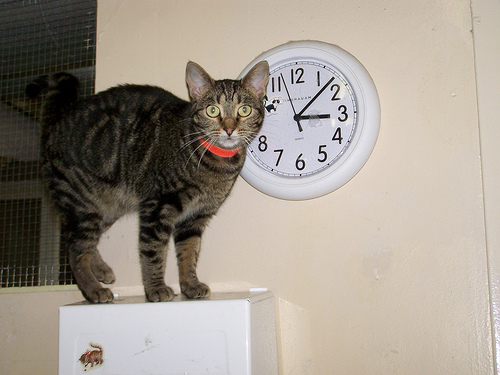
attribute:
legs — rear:
[32, 199, 282, 294]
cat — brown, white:
[1, 59, 270, 302]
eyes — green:
[204, 96, 260, 122]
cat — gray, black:
[27, 58, 272, 304]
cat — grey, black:
[39, 70, 291, 222]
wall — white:
[96, 2, 499, 373]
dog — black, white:
[261, 94, 281, 115]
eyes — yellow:
[204, 104, 252, 119]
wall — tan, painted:
[2, 7, 499, 374]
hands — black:
[277, 67, 346, 135]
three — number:
[332, 104, 352, 126]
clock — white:
[230, 33, 392, 207]